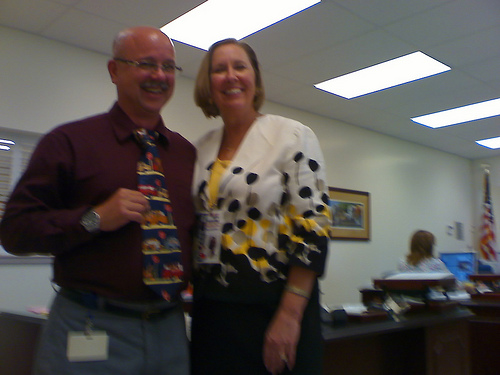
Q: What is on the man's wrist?
A: A watch.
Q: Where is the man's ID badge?
A: Clipped to his pants.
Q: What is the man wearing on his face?
A: Glasses.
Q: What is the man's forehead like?
A: Shiny.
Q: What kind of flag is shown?
A: American.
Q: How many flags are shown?
A: One.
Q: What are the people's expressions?
A: Smiling.